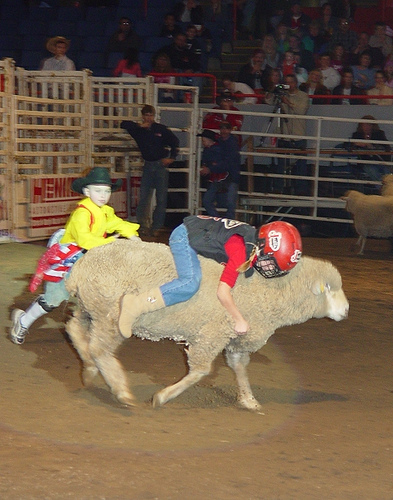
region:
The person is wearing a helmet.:
[237, 208, 321, 284]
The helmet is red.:
[248, 213, 317, 288]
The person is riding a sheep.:
[60, 206, 364, 446]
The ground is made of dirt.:
[123, 425, 369, 498]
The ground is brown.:
[158, 429, 385, 496]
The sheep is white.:
[65, 234, 358, 424]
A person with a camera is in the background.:
[259, 78, 297, 158]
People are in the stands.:
[115, 3, 392, 105]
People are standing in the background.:
[118, 90, 248, 235]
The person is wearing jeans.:
[114, 206, 311, 371]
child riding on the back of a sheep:
[65, 211, 347, 409]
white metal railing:
[146, 83, 390, 261]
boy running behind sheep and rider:
[6, 150, 350, 416]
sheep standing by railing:
[334, 141, 391, 254]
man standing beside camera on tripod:
[253, 72, 312, 198]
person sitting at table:
[328, 109, 391, 198]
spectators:
[87, 1, 392, 105]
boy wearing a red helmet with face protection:
[251, 215, 306, 280]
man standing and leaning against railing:
[116, 99, 182, 238]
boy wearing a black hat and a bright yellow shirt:
[64, 164, 138, 261]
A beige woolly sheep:
[54, 253, 361, 405]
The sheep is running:
[54, 249, 354, 402]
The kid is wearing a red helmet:
[124, 221, 329, 333]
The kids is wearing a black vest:
[150, 220, 295, 277]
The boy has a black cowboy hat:
[48, 160, 150, 241]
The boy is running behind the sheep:
[32, 153, 153, 354]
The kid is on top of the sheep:
[92, 215, 323, 340]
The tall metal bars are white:
[6, 57, 383, 262]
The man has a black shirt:
[123, 97, 176, 172]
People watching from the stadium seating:
[42, 7, 381, 116]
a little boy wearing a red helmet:
[261, 219, 310, 278]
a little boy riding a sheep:
[74, 213, 379, 419]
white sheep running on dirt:
[76, 237, 356, 421]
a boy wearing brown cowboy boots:
[112, 285, 170, 336]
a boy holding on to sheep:
[80, 207, 361, 337]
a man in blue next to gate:
[120, 100, 169, 228]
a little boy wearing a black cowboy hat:
[69, 165, 130, 186]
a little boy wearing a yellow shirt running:
[61, 200, 146, 238]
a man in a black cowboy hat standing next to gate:
[200, 121, 237, 213]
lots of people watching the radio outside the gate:
[3, 4, 392, 219]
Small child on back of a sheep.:
[59, 221, 348, 424]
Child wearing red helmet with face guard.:
[254, 217, 304, 281]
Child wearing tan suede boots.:
[115, 281, 180, 341]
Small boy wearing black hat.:
[68, 159, 125, 195]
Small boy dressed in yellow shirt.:
[56, 194, 141, 255]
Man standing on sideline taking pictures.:
[256, 74, 321, 213]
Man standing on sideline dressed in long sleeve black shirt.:
[118, 114, 185, 166]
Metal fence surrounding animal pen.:
[236, 107, 390, 234]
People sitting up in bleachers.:
[250, 14, 391, 93]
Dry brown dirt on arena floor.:
[154, 432, 389, 484]